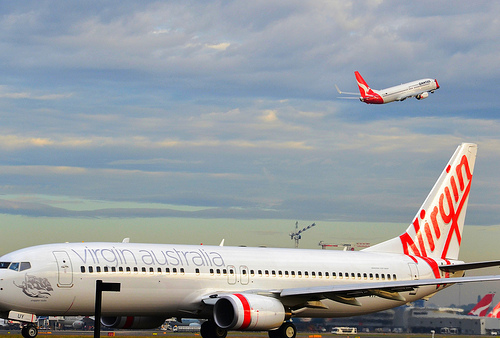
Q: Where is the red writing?
A: On the airplane tail.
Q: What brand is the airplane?
A: Virgin Australia.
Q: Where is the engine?
A: Under the wing.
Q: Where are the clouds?
A: In the sky.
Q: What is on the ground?
A: An airplane.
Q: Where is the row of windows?
A: On the airplane.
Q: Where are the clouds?
A: In the sky.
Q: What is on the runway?
A: A plane.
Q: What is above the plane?
A: A jet plane.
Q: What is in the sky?
A: Clouds.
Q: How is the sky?
A: Clear.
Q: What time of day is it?
A: It is day time.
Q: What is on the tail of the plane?
A: Red lettering.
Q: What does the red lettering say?
A: Virgin.